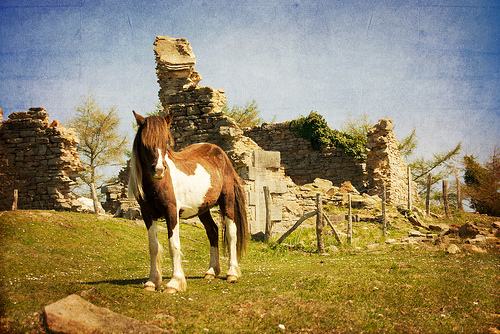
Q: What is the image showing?
A: It is showing a field.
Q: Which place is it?
A: It is a field.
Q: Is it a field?
A: Yes, it is a field.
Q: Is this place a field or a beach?
A: It is a field.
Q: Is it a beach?
A: No, it is a field.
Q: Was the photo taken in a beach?
A: No, the picture was taken in a field.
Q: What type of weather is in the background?
A: It is clear.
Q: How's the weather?
A: It is clear.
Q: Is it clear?
A: Yes, it is clear.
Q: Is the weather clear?
A: Yes, it is clear.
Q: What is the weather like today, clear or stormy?
A: It is clear.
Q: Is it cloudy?
A: No, it is clear.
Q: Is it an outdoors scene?
A: Yes, it is outdoors.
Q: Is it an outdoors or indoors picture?
A: It is outdoors.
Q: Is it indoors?
A: No, it is outdoors.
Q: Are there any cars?
A: No, there are no cars.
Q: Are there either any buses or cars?
A: No, there are no cars or buses.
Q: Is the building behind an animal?
A: Yes, the building is behind an animal.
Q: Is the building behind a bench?
A: No, the building is behind an animal.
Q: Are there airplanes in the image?
A: No, there are no airplanes.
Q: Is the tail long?
A: Yes, the tail is long.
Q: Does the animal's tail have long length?
A: Yes, the tail is long.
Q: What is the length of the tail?
A: The tail is long.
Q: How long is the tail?
A: The tail is long.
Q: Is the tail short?
A: No, the tail is long.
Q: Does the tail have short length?
A: No, the tail is long.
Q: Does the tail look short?
A: No, the tail is long.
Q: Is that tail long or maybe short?
A: The tail is long.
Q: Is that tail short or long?
A: The tail is long.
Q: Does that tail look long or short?
A: The tail is long.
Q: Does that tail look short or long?
A: The tail is long.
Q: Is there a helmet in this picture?
A: No, there are no helmets.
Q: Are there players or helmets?
A: No, there are no helmets or players.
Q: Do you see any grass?
A: Yes, there is grass.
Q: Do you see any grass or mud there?
A: Yes, there is grass.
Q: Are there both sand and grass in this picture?
A: No, there is grass but no sand.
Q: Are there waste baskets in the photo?
A: No, there are no waste baskets.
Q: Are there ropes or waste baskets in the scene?
A: No, there are no waste baskets or ropes.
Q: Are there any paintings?
A: No, there are no paintings.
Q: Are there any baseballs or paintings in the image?
A: No, there are no paintings or baseballs.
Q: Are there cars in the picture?
A: No, there are no cars.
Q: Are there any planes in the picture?
A: No, there are no planes.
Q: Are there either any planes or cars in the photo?
A: No, there are no planes or cars.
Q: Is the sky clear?
A: Yes, the sky is clear.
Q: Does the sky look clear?
A: Yes, the sky is clear.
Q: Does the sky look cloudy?
A: No, the sky is clear.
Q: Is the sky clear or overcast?
A: The sky is clear.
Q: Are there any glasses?
A: No, there are no glasses.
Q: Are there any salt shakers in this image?
A: No, there are no salt shakers.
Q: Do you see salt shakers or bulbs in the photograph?
A: No, there are no salt shakers or bulbs.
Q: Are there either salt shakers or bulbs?
A: No, there are no salt shakers or bulbs.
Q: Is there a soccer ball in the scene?
A: No, there are no soccer balls.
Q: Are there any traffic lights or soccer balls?
A: No, there are no soccer balls or traffic lights.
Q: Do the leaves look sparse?
A: Yes, the leaves are sparse.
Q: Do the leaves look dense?
A: No, the leaves are sparse.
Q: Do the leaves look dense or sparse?
A: The leaves are sparse.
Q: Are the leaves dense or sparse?
A: The leaves are sparse.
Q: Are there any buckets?
A: No, there are no buckets.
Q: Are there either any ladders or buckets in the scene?
A: No, there are no buckets or ladders.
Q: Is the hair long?
A: Yes, the hair is long.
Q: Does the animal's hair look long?
A: Yes, the hair is long.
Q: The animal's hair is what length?
A: The hair is long.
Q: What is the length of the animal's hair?
A: The hair is long.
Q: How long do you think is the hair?
A: The hair is long.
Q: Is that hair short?
A: No, the hair is long.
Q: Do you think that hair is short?
A: No, the hair is long.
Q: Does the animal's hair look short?
A: No, the hair is long.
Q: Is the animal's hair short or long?
A: The hair is long.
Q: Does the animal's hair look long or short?
A: The hair is long.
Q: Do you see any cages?
A: No, there are no cages.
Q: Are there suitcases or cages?
A: No, there are no cages or suitcases.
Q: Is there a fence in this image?
A: Yes, there is a fence.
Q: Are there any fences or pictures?
A: Yes, there is a fence.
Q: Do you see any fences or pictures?
A: Yes, there is a fence.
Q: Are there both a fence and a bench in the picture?
A: No, there is a fence but no benches.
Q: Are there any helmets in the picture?
A: No, there are no helmets.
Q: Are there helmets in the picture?
A: No, there are no helmets.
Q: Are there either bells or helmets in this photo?
A: No, there are no helmets or bells.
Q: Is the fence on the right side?
A: Yes, the fence is on the right of the image.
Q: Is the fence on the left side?
A: No, the fence is on the right of the image.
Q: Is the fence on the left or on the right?
A: The fence is on the right of the image.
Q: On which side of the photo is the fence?
A: The fence is on the right of the image.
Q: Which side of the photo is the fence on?
A: The fence is on the right of the image.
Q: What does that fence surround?
A: The fence surrounds the rock.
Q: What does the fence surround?
A: The fence surrounds the rock.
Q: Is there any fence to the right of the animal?
A: Yes, there is a fence to the right of the animal.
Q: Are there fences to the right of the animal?
A: Yes, there is a fence to the right of the animal.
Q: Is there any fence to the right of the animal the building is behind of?
A: Yes, there is a fence to the right of the animal.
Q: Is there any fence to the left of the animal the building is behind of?
A: No, the fence is to the right of the animal.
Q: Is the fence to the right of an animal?
A: Yes, the fence is to the right of an animal.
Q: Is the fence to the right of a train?
A: No, the fence is to the right of an animal.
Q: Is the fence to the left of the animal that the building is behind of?
A: No, the fence is to the right of the animal.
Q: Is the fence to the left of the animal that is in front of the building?
A: No, the fence is to the right of the animal.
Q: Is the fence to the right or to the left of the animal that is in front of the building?
A: The fence is to the right of the animal.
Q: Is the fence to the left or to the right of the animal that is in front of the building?
A: The fence is to the right of the animal.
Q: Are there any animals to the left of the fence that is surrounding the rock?
A: Yes, there is an animal to the left of the fence.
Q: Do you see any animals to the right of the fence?
A: No, the animal is to the left of the fence.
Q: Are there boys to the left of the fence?
A: No, there is an animal to the left of the fence.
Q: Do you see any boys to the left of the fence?
A: No, there is an animal to the left of the fence.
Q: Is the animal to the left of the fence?
A: Yes, the animal is to the left of the fence.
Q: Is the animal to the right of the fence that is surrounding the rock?
A: No, the animal is to the left of the fence.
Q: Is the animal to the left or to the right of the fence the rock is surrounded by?
A: The animal is to the left of the fence.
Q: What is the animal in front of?
A: The animal is in front of the building.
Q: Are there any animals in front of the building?
A: Yes, there is an animal in front of the building.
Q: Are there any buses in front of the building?
A: No, there is an animal in front of the building.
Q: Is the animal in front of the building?
A: Yes, the animal is in front of the building.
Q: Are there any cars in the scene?
A: No, there are no cars.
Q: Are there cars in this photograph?
A: No, there are no cars.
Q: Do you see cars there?
A: No, there are no cars.